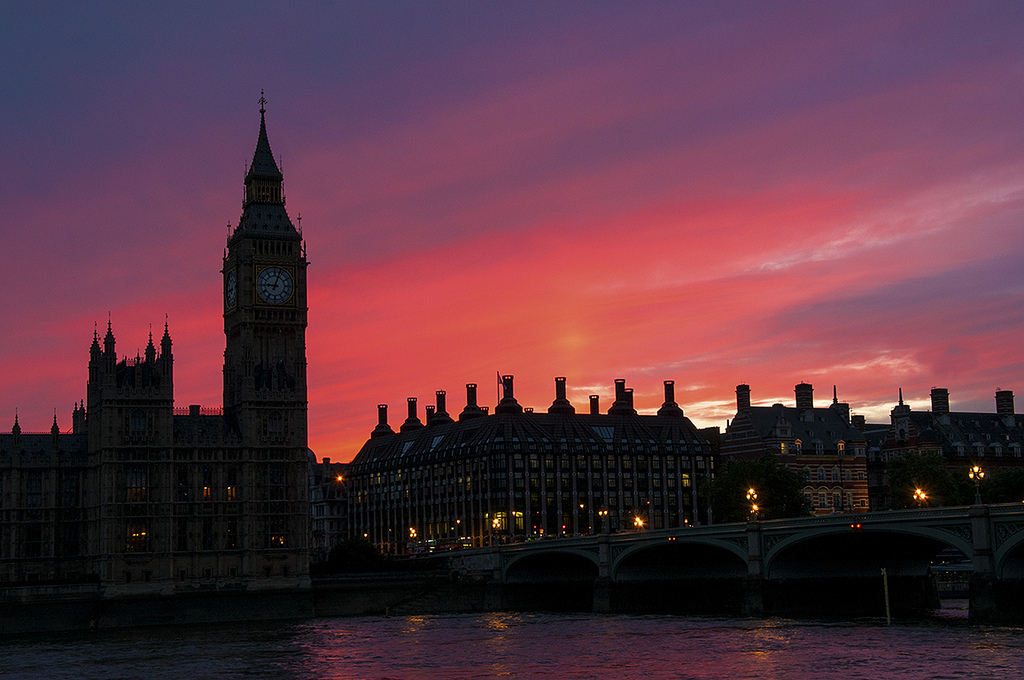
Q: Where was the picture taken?
A: London.